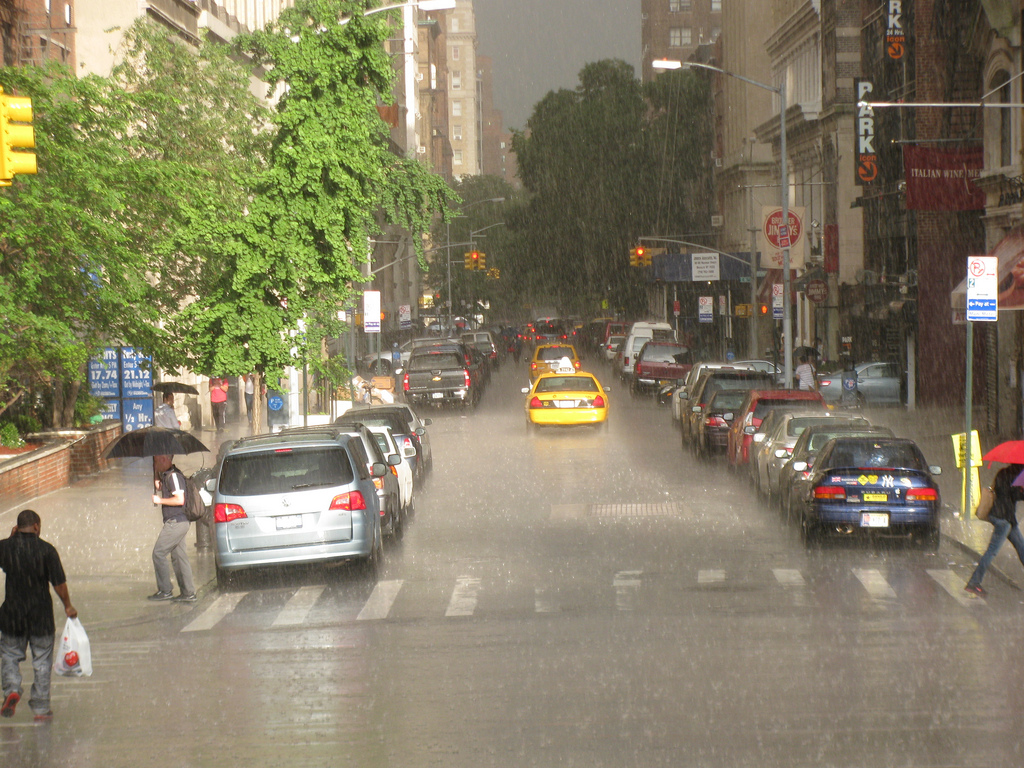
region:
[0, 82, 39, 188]
yellow traffic light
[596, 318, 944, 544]
line of parked cars to the right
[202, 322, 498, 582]
line of parked cars to the left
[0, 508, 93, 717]
man without umbrella carrying plastic bag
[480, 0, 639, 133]
dark gray cloudy sky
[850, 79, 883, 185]
vertical parking sign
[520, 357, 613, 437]
yellow taxi in middle of road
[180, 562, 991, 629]
crosswalk stripes on the road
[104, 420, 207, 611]
man with backpack under black umbrella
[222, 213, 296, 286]
green leaves on the tree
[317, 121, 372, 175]
green leaves on the tree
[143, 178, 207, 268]
green leaves on the tree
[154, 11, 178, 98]
green leaves on the tree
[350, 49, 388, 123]
green leaves on the tree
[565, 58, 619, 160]
green leaves on the tree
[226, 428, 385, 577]
a car is parked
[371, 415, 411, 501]
a car is parked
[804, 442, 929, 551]
a car is parked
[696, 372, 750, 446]
a car is parked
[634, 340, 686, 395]
a car is parked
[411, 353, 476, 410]
a car is parked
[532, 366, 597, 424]
A car is driving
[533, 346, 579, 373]
A car is driving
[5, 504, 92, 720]
a man is walking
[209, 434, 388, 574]
A car on a street.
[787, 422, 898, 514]
A car on a street.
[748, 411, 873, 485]
A car on a street.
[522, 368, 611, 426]
A car on a street.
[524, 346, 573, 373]
A car on a street.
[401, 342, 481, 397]
A car on a street.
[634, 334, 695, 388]
A car on a street.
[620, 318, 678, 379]
A car on a street.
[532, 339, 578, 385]
taxi in front of taxi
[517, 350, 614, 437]
taxi behind taxi on road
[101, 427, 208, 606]
person holding black umbrella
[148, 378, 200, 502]
person holding black umbrella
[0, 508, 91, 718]
person holding white bag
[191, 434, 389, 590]
car parked next to sidewalk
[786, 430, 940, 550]
car parked next to sidewalk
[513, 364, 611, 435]
taxi driving in the rain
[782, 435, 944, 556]
car parked on the curb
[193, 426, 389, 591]
van parked on curb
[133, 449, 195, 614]
man walking in the rain carrying an umbrella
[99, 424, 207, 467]
umbrella man is carrying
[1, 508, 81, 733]
man walking in the rain without an umbrella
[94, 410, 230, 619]
A man with a black umbrella crosses the road.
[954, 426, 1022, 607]
A person with a red umbrella crossing the road.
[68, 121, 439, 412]
Sun on the tree in the rain.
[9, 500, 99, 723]
A man with a plastic bag has no umbrella.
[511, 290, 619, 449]
Cars driving on a one way road.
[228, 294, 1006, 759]
A wet road in a city.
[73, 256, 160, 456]
A blue sign with white writing.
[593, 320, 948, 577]
Cars parked on the right side of the road.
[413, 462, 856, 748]
The ground is wet.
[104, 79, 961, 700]
it is raining outside.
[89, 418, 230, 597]
A person under the umbrella.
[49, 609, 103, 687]
The plastic bag is white and red.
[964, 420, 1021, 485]
The umbrella is red.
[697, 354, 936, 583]
Cars parked on the side of the red.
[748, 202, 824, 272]
A red and white sign on the pole.